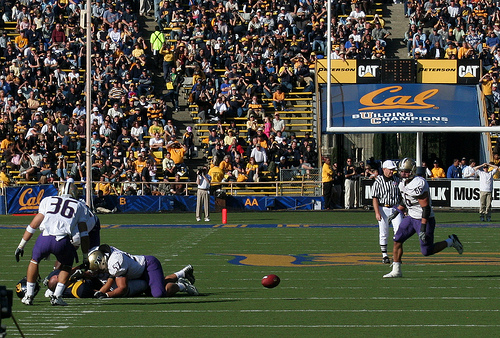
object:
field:
[0, 210, 499, 338]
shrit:
[396, 175, 437, 218]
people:
[223, 128, 239, 146]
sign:
[354, 84, 440, 111]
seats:
[291, 119, 308, 124]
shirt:
[206, 165, 224, 186]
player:
[380, 156, 463, 279]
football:
[260, 272, 282, 288]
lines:
[0, 308, 500, 314]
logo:
[204, 250, 499, 269]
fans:
[271, 85, 287, 113]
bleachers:
[0, 0, 499, 214]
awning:
[320, 84, 481, 132]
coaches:
[248, 141, 268, 168]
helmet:
[395, 157, 418, 179]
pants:
[391, 214, 448, 257]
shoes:
[382, 268, 404, 277]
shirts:
[49, 28, 65, 44]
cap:
[379, 159, 400, 172]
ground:
[0, 213, 499, 338]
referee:
[369, 158, 406, 266]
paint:
[254, 255, 283, 264]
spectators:
[131, 41, 145, 58]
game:
[0, 176, 500, 336]